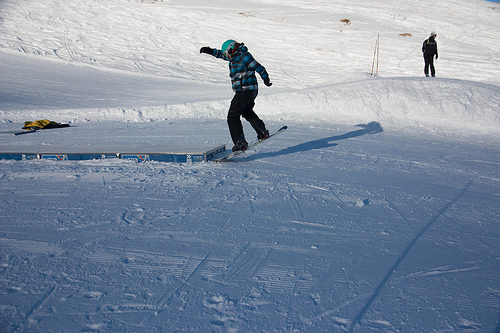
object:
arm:
[208, 48, 229, 61]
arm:
[246, 57, 268, 79]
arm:
[422, 42, 426, 52]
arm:
[435, 44, 437, 56]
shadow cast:
[223, 121, 383, 163]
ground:
[0, 117, 498, 333]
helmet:
[222, 39, 239, 58]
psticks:
[371, 33, 380, 75]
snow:
[0, 0, 500, 333]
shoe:
[232, 140, 247, 151]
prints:
[196, 290, 246, 330]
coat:
[22, 119, 70, 129]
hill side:
[0, 0, 500, 129]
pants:
[226, 93, 266, 144]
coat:
[212, 43, 269, 91]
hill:
[0, 0, 500, 133]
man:
[199, 40, 270, 151]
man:
[422, 33, 438, 78]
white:
[264, 196, 418, 316]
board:
[226, 126, 287, 160]